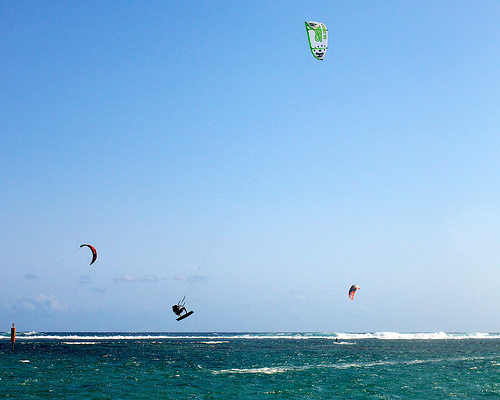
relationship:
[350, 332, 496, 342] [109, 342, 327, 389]
white surf on ocean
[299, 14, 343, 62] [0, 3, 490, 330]
kite in sky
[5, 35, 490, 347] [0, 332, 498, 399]
skies over ocean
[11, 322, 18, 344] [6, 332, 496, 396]
pole in water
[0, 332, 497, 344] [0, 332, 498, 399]
white waves of ocean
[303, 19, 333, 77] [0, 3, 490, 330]
kite in sky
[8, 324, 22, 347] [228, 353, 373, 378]
pole in water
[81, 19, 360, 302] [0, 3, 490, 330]
kite in sky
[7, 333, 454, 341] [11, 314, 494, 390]
foam of ocean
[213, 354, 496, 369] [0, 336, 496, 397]
foam in foreground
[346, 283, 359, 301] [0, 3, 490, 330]
kite in sky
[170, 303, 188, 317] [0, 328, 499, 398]
skier airborne over water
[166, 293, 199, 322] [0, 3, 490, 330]
skier in sky